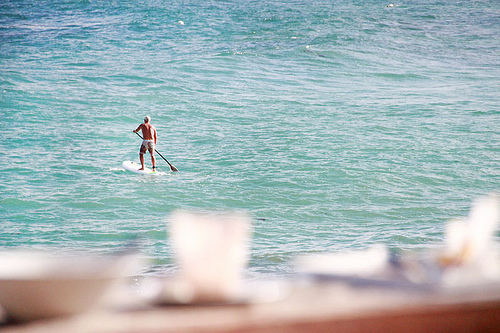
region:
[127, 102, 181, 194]
man is on surfboard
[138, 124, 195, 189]
man is holding paddle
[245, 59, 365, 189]
water is light blue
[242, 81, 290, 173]
small waves on water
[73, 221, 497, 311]
brown table in fore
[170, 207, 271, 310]
white cup on table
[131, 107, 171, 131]
man has white hat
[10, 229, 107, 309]
white bowl on table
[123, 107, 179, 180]
man rowing a surfboard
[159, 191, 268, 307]
drink cup on a ledge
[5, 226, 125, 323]
bowl on a ledge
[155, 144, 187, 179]
oar in man's hands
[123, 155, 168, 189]
white surfboard in the water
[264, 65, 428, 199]
water of an ocean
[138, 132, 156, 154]
swim trunks of a man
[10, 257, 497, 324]
ledge in front of ocean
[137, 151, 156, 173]
legs of a man on surfboard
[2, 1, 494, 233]
Bluish-green ocean water.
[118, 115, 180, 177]
Man in the ocean.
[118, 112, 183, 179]
Man on a paddle board.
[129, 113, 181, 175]
Man holding a paddle.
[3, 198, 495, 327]
Blurry objects on a ledge.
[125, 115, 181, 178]
A man in swim trunks.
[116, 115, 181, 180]
Man with no shirt on.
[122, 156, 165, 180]
A white paddle board.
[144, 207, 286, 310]
Blurry cup and saucer.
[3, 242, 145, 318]
Blurry bowl on a ledge.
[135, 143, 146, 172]
the leg of a person surfing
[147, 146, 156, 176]
the leg of a person surfing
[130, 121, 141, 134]
the arm of a person surfing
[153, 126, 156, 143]
the arm of a person surfing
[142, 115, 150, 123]
the head of a person surfing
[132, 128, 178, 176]
the paddle of a person surfing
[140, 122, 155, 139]
the back of a person surfing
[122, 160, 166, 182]
the surfboard of a person surfing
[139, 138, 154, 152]
the shorts of a person surfing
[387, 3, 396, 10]
a white ball in the water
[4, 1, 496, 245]
rough surface of water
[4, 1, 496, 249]
blue water of ocean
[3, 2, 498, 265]
light reflection on water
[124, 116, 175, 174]
person standing on paddleboard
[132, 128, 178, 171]
hand on end of oar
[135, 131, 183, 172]
paddle partially in water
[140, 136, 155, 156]
shorts on man's body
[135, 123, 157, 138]
bare back of man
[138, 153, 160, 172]
cable tied to man's leg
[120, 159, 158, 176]
surface of white paddleboard